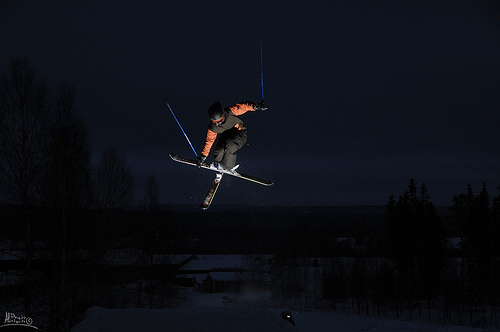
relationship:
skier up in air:
[192, 100, 270, 177] [2, 3, 497, 331]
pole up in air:
[253, 31, 271, 115] [2, 3, 497, 331]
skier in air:
[192, 100, 270, 177] [2, 3, 497, 331]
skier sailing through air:
[192, 100, 270, 177] [2, 3, 497, 331]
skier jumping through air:
[192, 100, 270, 177] [2, 3, 497, 331]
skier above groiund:
[192, 100, 270, 177] [1, 273, 499, 332]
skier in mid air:
[192, 100, 270, 177] [2, 3, 497, 331]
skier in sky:
[192, 100, 270, 177] [3, 4, 499, 196]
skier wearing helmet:
[192, 100, 270, 177] [206, 102, 229, 129]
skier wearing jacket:
[192, 100, 270, 177] [204, 101, 261, 158]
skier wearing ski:
[192, 100, 270, 177] [165, 147, 279, 195]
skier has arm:
[192, 100, 270, 177] [227, 99, 270, 119]